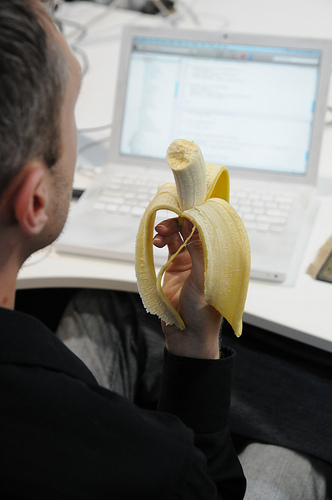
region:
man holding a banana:
[121, 129, 239, 315]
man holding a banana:
[131, 134, 220, 257]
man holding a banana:
[134, 136, 247, 330]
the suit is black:
[24, 327, 250, 486]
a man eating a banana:
[5, 2, 257, 498]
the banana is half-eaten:
[136, 128, 255, 343]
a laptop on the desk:
[77, 20, 324, 279]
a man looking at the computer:
[0, 1, 299, 497]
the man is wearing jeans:
[65, 292, 326, 499]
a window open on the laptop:
[125, 37, 317, 166]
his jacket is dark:
[10, 302, 294, 499]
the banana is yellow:
[114, 127, 259, 348]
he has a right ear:
[11, 156, 59, 243]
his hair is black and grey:
[1, 7, 70, 193]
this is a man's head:
[0, 3, 82, 249]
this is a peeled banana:
[132, 136, 252, 338]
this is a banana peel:
[185, 196, 252, 338]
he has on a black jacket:
[1, 308, 247, 499]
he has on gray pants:
[58, 285, 328, 496]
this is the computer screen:
[103, 22, 331, 187]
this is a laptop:
[52, 20, 331, 284]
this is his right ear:
[12, 168, 50, 236]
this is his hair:
[1, 0, 70, 194]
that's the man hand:
[150, 215, 227, 335]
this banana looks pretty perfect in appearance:
[130, 134, 255, 340]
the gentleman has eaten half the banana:
[161, 131, 211, 209]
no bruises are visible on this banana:
[161, 134, 213, 215]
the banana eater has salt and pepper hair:
[0, 0, 69, 199]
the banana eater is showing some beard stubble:
[20, 161, 77, 257]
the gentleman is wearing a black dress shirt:
[0, 300, 253, 498]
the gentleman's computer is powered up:
[53, 16, 330, 289]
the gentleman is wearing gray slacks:
[49, 289, 331, 496]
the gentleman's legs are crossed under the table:
[50, 287, 331, 499]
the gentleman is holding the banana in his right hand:
[145, 205, 231, 357]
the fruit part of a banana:
[156, 126, 218, 210]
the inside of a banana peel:
[197, 216, 244, 278]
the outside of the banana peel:
[210, 174, 233, 199]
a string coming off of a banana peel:
[159, 231, 194, 275]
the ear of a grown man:
[14, 156, 50, 232]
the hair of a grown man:
[13, 74, 49, 144]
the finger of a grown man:
[161, 207, 183, 250]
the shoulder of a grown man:
[64, 363, 219, 499]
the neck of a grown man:
[0, 277, 29, 324]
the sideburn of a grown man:
[33, 102, 69, 174]